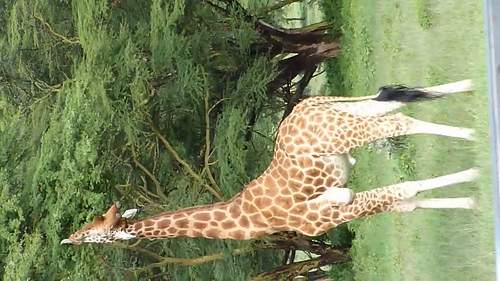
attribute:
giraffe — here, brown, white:
[53, 75, 474, 250]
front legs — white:
[364, 169, 475, 221]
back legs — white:
[351, 80, 474, 141]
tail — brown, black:
[320, 79, 426, 104]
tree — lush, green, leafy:
[2, 2, 349, 278]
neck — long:
[135, 187, 251, 247]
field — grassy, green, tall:
[322, 4, 496, 279]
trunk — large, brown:
[268, 15, 333, 75]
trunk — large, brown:
[282, 231, 342, 273]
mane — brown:
[140, 196, 225, 224]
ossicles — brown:
[86, 205, 104, 227]